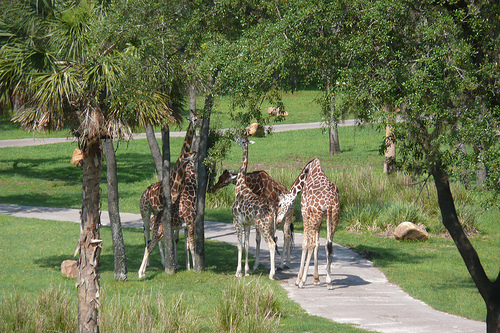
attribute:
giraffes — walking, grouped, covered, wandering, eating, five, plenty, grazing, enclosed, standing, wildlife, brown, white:
[135, 115, 346, 288]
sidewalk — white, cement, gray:
[1, 185, 497, 331]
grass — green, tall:
[0, 212, 366, 332]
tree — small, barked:
[149, 0, 181, 279]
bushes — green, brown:
[215, 158, 483, 223]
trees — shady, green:
[0, 4, 264, 332]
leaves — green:
[198, 131, 242, 209]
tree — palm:
[0, 0, 173, 330]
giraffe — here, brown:
[141, 110, 203, 282]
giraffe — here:
[229, 111, 282, 283]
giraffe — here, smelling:
[280, 157, 343, 289]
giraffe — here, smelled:
[215, 169, 295, 271]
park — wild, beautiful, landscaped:
[1, 5, 499, 329]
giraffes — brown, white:
[209, 157, 335, 292]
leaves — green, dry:
[331, 4, 494, 176]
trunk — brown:
[383, 102, 397, 176]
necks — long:
[174, 131, 263, 181]